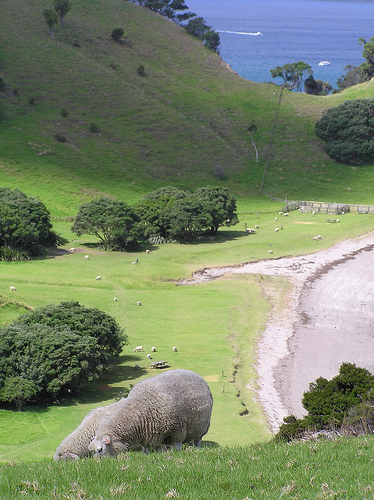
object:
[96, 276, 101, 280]
sheep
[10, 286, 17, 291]
sheep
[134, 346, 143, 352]
sheep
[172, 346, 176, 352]
sheep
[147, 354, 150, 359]
sheep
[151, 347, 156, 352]
sheep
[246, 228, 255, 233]
sheep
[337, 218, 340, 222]
sheep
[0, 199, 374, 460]
pasteur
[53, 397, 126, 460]
sheep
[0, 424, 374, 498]
hill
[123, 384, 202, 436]
coat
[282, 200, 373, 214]
sheep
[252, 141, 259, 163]
log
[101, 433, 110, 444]
indentification tag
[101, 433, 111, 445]
sheep's ear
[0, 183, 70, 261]
tree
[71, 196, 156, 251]
tree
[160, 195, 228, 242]
tree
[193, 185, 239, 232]
tree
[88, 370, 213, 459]
sheep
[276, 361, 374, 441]
tree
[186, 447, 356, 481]
grass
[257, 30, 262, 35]
boat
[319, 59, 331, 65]
boat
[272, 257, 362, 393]
sand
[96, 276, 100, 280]
sheep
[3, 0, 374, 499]
valley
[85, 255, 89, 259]
sheep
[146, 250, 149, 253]
sheep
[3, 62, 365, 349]
field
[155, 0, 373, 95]
water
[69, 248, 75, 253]
sheep